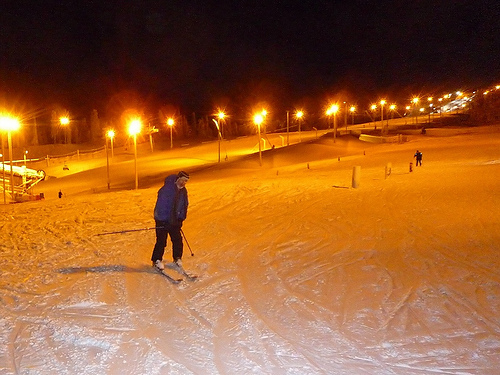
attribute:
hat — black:
[176, 167, 192, 179]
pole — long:
[131, 126, 144, 195]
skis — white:
[162, 264, 199, 288]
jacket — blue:
[154, 192, 171, 222]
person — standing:
[152, 168, 204, 289]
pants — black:
[148, 220, 185, 262]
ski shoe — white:
[154, 261, 168, 271]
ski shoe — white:
[172, 256, 184, 268]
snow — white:
[0, 109, 497, 373]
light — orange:
[320, 94, 342, 144]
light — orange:
[289, 107, 307, 129]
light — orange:
[246, 102, 271, 151]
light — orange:
[158, 111, 182, 149]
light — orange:
[118, 108, 148, 189]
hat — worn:
[173, 166, 188, 181]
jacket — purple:
[154, 173, 191, 230]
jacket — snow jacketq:
[149, 172, 189, 227]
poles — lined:
[1, 90, 496, 222]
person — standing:
[154, 171, 204, 253]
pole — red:
[91, 220, 163, 246]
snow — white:
[185, 291, 271, 360]